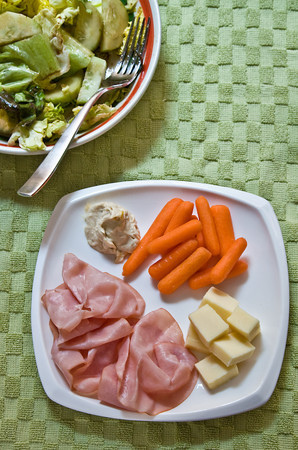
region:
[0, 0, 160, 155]
ceramic bowl with salad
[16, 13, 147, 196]
shiny silver fork in bowl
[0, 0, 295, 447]
green checkered table cloth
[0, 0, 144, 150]
mixed salad in bowl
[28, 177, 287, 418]
square white plate with food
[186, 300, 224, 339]
cubed cheese near ham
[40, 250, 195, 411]
sliced ham on plate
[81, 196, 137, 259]
yellowish dip on white plate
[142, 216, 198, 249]
peeled baby carrot on plate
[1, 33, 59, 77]
chopped lettuce in salad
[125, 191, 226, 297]
Carrots on a plate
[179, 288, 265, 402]
Cheese on a plate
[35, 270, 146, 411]
Ham on a plate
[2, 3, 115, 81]
Salad on the plate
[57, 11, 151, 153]
A fork for the salad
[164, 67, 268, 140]
Green table cloth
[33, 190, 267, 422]
A white plate with food on it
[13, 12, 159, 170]
A hard plate with food on it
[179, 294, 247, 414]
The cheese is square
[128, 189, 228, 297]
The carrots are orange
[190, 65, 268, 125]
white checkered tan cloth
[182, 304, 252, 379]
cube pieces of American cheeses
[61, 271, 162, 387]
layers of pin fresh ham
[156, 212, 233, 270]
couple of carrots niblets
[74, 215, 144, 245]
a dab of fresh ranch dip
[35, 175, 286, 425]
square plate with rounded edges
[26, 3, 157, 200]
silver fork on plate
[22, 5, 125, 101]
a plate of fruit salad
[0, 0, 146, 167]
red and white round plate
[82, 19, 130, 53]
pieces of kiwi fruit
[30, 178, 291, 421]
plate with carrots, meat, and cheese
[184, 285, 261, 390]
white cheese cubes on plate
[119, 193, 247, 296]
orange carrots on plate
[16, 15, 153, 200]
silver fork on side of plate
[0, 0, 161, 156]
plate with orange ring around edge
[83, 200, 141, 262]
grey dip next to carrots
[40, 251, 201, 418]
pink lunch meat next to cheese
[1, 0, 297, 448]
green tablecloth under plates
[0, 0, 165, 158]
mixed greens on round plate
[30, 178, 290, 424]
white plate on green tablecloth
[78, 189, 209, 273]
Carrots with hummus dip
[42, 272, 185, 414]
lunch meat ham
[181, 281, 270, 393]
cubed cheese bits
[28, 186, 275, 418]
plate with carrots, hummus, cheese, and ham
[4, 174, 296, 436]
plate of food sitting on a towel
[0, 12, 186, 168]
bowl of salad with a fork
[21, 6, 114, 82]
salad with lettuce and cucumber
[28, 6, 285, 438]
healthy meal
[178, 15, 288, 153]
towel with a square patern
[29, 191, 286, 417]
Plate of food